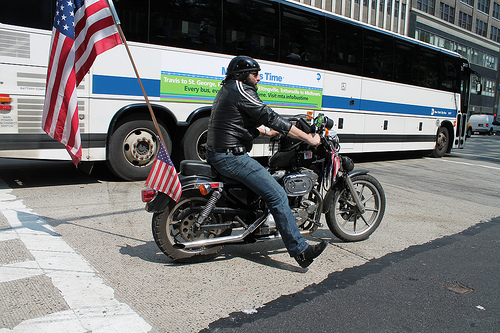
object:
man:
[206, 55, 331, 269]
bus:
[0, 2, 482, 182]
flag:
[41, 1, 124, 169]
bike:
[143, 113, 387, 263]